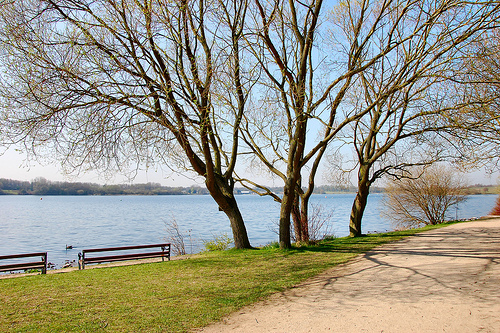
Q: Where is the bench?
A: The grass.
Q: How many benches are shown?
A: Two.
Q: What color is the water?
A: Blue.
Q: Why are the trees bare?
A: It's autumn.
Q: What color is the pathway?
A: Tan.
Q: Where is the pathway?
A: Next to grass.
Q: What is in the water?
A: A duck.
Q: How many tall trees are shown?
A: Four.